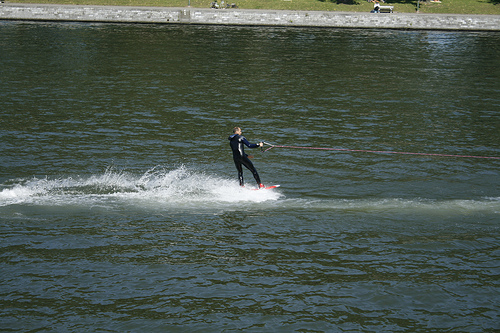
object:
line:
[274, 145, 499, 160]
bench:
[373, 4, 394, 13]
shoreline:
[0, 2, 499, 32]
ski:
[228, 126, 281, 191]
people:
[211, 0, 235, 10]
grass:
[246, 0, 325, 10]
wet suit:
[227, 134, 262, 187]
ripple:
[0, 19, 500, 333]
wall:
[0, 5, 498, 29]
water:
[1, 17, 497, 331]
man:
[228, 126, 267, 190]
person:
[374, 2, 382, 14]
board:
[242, 183, 281, 192]